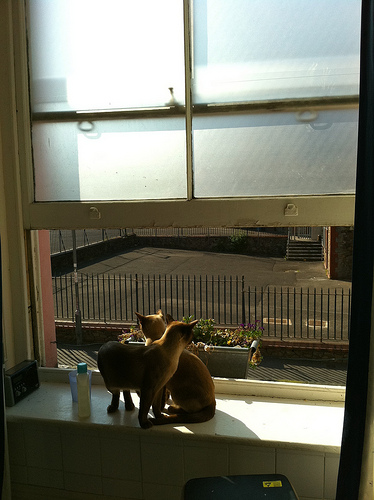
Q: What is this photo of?
A: An open window.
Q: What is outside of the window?
A: Plants.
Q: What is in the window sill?
A: Cats.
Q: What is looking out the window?
A: Two cats.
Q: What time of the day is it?
A: It is day time.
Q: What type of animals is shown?
A: Cats.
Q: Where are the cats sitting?
A: In the window.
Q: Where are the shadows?
A: Behind the cat on the right.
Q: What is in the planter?
A: A plant.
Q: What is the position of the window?
A: Raised.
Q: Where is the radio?
A: Left corner of the window.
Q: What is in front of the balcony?
A: Railing.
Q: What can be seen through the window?
A: Paved lot and a building.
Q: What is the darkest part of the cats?
A: The ears.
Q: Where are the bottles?
A: Beside the cats.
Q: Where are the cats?
A: Window ledge.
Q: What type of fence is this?
A: Wrought iron.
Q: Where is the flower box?
A: Outside window ledge.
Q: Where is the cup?
A: Left of cats.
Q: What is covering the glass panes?
A: White paper.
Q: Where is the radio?
A: Left on ledge.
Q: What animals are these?
A: Cats.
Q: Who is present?
A: No one.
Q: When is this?
A: Daytime.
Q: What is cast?
A: Shadows.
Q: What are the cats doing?
A: Bonding.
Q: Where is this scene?
A: In an open window.